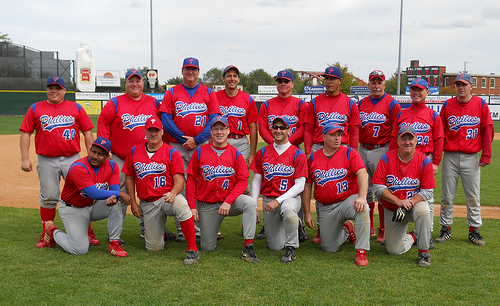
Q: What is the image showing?
A: It is showing a field.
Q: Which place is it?
A: It is a field.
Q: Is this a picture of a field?
A: Yes, it is showing a field.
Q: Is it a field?
A: Yes, it is a field.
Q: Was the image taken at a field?
A: Yes, it was taken in a field.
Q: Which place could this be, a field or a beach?
A: It is a field.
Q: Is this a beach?
A: No, it is a field.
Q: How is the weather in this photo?
A: It is clear.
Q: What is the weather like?
A: It is clear.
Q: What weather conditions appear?
A: It is clear.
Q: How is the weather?
A: It is clear.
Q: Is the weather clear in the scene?
A: Yes, it is clear.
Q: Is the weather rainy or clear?
A: It is clear.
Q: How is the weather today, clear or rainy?
A: It is clear.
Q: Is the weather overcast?
A: No, it is clear.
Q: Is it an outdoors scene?
A: Yes, it is outdoors.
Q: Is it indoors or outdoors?
A: It is outdoors.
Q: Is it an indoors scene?
A: No, it is outdoors.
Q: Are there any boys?
A: No, there are no boys.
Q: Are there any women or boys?
A: No, there are no boys or women.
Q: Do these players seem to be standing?
A: Yes, the players are standing.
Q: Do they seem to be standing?
A: Yes, the players are standing.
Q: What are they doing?
A: The players are standing.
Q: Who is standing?
A: The players are standing.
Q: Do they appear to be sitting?
A: No, the players are standing.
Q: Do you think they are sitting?
A: No, the players are standing.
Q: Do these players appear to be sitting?
A: No, the players are standing.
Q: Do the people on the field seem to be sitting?
A: No, the players are standing.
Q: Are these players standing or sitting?
A: The players are standing.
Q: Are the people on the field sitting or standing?
A: The players are standing.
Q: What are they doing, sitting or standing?
A: The players are standing.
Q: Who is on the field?
A: The players are on the field.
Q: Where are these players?
A: The players are on the field.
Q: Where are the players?
A: The players are on the field.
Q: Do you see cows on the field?
A: No, there are players on the field.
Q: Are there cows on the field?
A: No, there are players on the field.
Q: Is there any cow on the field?
A: No, there are players on the field.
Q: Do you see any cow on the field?
A: No, there are players on the field.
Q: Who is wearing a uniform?
A: The players are wearing a uniform.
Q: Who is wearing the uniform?
A: The players are wearing a uniform.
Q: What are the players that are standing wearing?
A: The players are wearing a uniform.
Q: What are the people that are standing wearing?
A: The players are wearing a uniform.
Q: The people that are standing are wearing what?
A: The players are wearing a uniform.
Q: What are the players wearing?
A: The players are wearing a uniform.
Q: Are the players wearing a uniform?
A: Yes, the players are wearing a uniform.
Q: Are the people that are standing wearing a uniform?
A: Yes, the players are wearing a uniform.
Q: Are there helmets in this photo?
A: No, there are no helmets.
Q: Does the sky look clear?
A: Yes, the sky is clear.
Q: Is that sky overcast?
A: No, the sky is clear.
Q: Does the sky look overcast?
A: No, the sky is clear.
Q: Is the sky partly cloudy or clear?
A: The sky is clear.